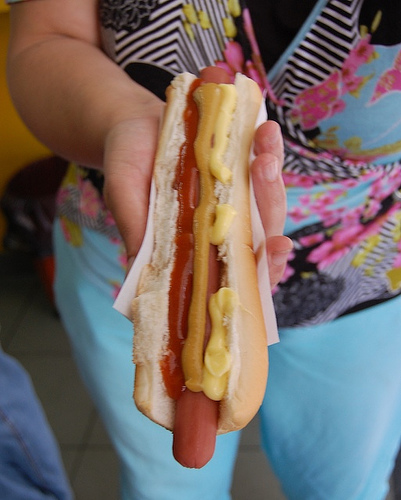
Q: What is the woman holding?
A: A hot dog.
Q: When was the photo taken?
A: During the day.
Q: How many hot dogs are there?
A: One.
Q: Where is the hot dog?
A: In the woman's hand.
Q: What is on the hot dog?
A: Ketchup and mustard.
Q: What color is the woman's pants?
A: Blue.